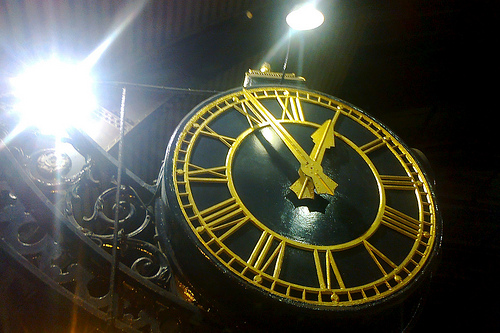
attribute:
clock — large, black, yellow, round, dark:
[156, 62, 452, 329]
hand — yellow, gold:
[291, 116, 339, 207]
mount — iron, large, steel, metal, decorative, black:
[1, 90, 196, 332]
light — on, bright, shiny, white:
[287, 2, 324, 34]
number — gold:
[357, 130, 387, 156]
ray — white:
[81, 4, 153, 60]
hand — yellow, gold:
[241, 89, 341, 202]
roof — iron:
[1, 2, 271, 81]